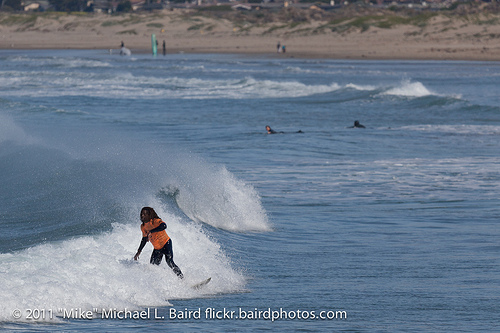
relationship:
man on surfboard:
[117, 199, 207, 297] [139, 280, 217, 290]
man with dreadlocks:
[132, 206, 186, 280] [139, 205, 157, 223]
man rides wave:
[132, 206, 186, 280] [4, 191, 262, 319]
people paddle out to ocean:
[255, 100, 391, 144] [0, 48, 499, 333]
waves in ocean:
[171, 58, 450, 119] [8, 55, 477, 316]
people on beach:
[108, 25, 296, 63] [0, 0, 493, 51]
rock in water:
[117, 41, 133, 60] [5, 47, 482, 318]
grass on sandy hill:
[291, 8, 461, 43] [138, 0, 478, 51]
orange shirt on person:
[138, 223, 184, 256] [123, 194, 225, 300]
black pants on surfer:
[155, 248, 191, 284] [125, 202, 189, 305]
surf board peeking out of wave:
[176, 250, 222, 296] [17, 223, 239, 324]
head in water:
[126, 199, 178, 259] [220, 163, 362, 247]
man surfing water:
[132, 206, 186, 280] [265, 175, 408, 193]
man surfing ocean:
[132, 206, 186, 280] [16, 69, 107, 249]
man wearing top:
[132, 206, 186, 280] [140, 214, 174, 243]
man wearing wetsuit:
[132, 206, 186, 280] [354, 120, 363, 145]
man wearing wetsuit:
[132, 206, 186, 280] [351, 109, 363, 132]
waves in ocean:
[0, 216, 243, 324] [26, 90, 72, 201]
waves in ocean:
[26, 279, 188, 306] [203, 165, 412, 329]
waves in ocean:
[0, 216, 243, 324] [11, 279, 382, 330]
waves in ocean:
[0, 216, 243, 324] [8, 122, 88, 238]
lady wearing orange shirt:
[104, 194, 208, 303] [139, 218, 171, 250]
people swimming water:
[264, 125, 305, 135] [32, 128, 134, 191]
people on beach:
[209, 29, 320, 60] [184, 20, 447, 77]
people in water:
[262, 114, 369, 135] [244, 94, 384, 161]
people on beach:
[275, 38, 282, 54] [190, 19, 359, 59]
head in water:
[261, 119, 281, 139] [226, 110, 320, 157]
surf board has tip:
[189, 276, 213, 291] [190, 270, 215, 295]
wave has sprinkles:
[173, 174, 271, 234] [133, 137, 205, 186]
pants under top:
[148, 238, 185, 279] [141, 223, 171, 248]